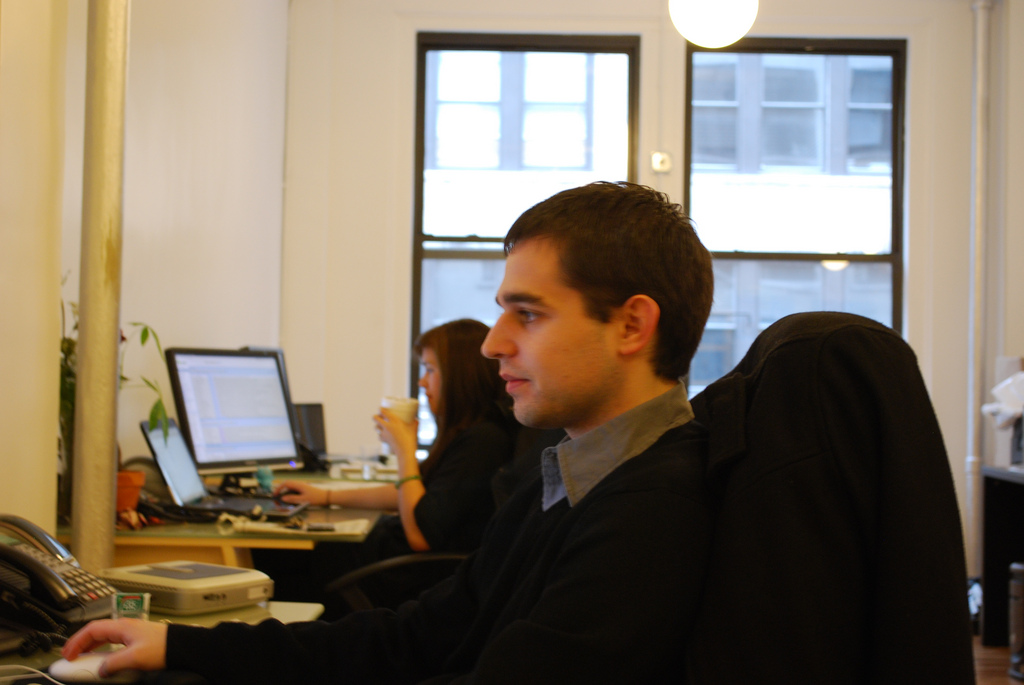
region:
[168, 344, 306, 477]
a desktop computer monitor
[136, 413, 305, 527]
an open laptop computer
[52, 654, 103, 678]
a white computer mouse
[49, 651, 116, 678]
a corded Apple Mighty Mouse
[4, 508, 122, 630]
a black desk phone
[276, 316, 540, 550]
a woman drinking from a cup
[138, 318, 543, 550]
a woman using a computer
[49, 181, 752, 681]
a man using a computer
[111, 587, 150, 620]
a package of breath mints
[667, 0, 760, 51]
an overhead ceiling light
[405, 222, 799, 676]
a man wearing a sweater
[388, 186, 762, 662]
a man wearing a black sweater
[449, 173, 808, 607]
a man wearing a collar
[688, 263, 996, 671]
a jacket on the chair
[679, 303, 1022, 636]
a black jacket on the chair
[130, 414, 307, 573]
a laptop is open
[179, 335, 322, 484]
a computer monitor on the desk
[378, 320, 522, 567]
a woman is holding a drink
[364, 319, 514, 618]
a woman sitting down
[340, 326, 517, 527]
a woman sitting at a desk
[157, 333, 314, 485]
the screen is turn on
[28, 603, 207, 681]
the hand on a mouse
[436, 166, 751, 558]
man has short hair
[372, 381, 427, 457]
the cup is white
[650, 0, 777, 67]
the light is white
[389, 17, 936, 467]
a window behind people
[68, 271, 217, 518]
leaves above a laptop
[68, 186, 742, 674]
the man is indoors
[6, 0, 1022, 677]
the scene takes place indoors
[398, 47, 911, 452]
the windows are large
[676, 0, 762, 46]
the light is on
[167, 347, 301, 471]
the screen is on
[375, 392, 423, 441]
the woman is drinking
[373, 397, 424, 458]
the woman has bracelet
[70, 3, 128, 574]
the pole is white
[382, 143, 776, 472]
head of a man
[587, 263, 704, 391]
ear of the man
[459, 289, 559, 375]
nose of the man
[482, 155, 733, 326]
brown hair on man's head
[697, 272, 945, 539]
clothing behind the man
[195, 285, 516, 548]
woman on her computer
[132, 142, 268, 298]
wall above the lady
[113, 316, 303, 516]
computer turned on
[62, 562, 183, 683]
hand of the man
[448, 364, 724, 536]
collar of the shirt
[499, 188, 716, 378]
brown hair on a man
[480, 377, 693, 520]
a blue shirt collar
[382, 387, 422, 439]
a white cup of coffee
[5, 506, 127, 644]
a corded grey phone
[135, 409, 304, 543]
a small black laptop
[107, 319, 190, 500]
a plant behind the computer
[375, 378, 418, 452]
White cup in woman's hand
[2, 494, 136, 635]
Phone on a desk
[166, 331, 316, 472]
Computer monitor on a desk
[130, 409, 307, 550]
Laptop on a table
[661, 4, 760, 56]
Light on the ceiling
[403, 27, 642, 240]
Window in a room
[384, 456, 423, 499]
Bracelet on a woman's arm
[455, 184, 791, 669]
Man sitting in a chair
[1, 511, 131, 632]
a black telephone